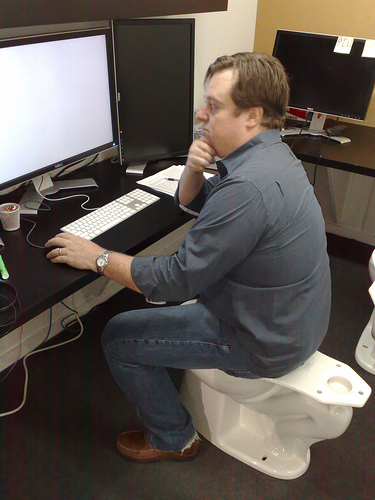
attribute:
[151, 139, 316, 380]
shirt — blue